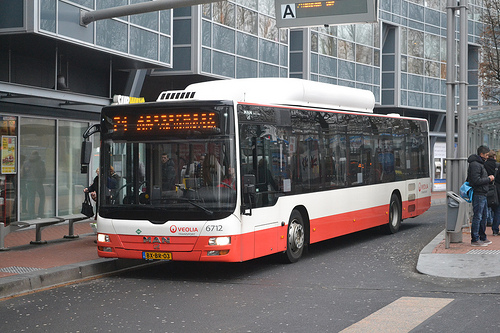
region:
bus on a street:
[72, 62, 442, 282]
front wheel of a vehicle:
[275, 200, 312, 265]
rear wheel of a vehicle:
[381, 185, 402, 236]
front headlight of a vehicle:
[205, 230, 235, 247]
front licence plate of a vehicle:
[135, 245, 175, 260]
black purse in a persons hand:
[75, 181, 95, 217]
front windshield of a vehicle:
[90, 95, 240, 225]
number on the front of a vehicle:
[200, 221, 227, 235]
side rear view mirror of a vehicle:
[70, 115, 100, 180]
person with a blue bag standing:
[452, 140, 493, 250]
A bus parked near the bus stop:
[97, 102, 440, 249]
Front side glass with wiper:
[103, 108, 229, 218]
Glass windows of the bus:
[243, 107, 426, 187]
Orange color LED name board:
[104, 108, 219, 136]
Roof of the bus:
[157, 82, 439, 122]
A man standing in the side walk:
[460, 135, 499, 249]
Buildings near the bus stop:
[21, 5, 482, 70]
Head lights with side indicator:
[92, 232, 229, 262]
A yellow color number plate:
[140, 250, 175, 262]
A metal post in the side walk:
[444, 5, 476, 239]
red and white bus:
[105, 80, 439, 262]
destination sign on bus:
[111, 111, 217, 134]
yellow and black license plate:
[143, 251, 170, 260]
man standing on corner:
[468, 146, 492, 243]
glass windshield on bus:
[106, 136, 234, 219]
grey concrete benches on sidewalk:
[19, 216, 87, 244]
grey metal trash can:
[448, 191, 464, 238]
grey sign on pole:
[276, 1, 377, 26]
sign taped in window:
[1, 136, 16, 174]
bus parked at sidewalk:
[111, 85, 431, 255]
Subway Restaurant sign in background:
[111, 93, 148, 109]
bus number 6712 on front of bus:
[205, 222, 224, 233]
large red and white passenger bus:
[96, 71, 429, 267]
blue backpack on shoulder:
[460, 174, 472, 202]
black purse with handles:
[82, 188, 93, 218]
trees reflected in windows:
[399, 25, 453, 77]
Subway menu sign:
[0, 133, 20, 173]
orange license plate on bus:
[143, 250, 173, 261]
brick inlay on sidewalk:
[34, 240, 91, 265]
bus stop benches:
[9, 209, 89, 248]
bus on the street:
[51, 78, 441, 281]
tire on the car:
[254, 202, 324, 271]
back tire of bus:
[359, 191, 419, 239]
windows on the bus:
[283, 133, 371, 183]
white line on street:
[378, 283, 456, 327]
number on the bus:
[201, 218, 233, 240]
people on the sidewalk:
[459, 144, 499, 209]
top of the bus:
[78, 91, 262, 150]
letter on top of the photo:
[266, 1, 307, 28]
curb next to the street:
[47, 257, 91, 294]